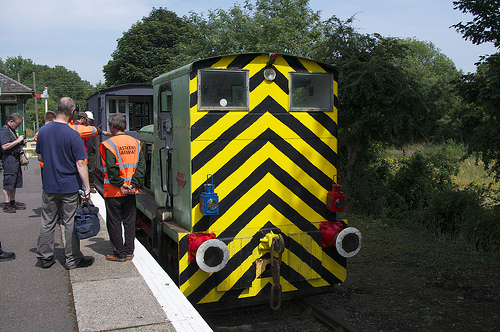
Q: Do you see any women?
A: No, there are no women.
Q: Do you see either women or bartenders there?
A: No, there are no women or bartenders.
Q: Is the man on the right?
A: No, the man is on the left of the image.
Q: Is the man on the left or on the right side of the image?
A: The man is on the left of the image.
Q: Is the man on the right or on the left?
A: The man is on the left of the image.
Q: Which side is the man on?
A: The man is on the left of the image.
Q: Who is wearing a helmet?
A: The man is wearing a helmet.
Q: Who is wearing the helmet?
A: The man is wearing a helmet.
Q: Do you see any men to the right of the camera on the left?
A: Yes, there is a man to the right of the camera.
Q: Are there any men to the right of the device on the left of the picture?
A: Yes, there is a man to the right of the camera.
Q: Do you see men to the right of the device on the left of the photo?
A: Yes, there is a man to the right of the camera.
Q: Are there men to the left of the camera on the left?
A: No, the man is to the right of the camera.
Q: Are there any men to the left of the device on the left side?
A: No, the man is to the right of the camera.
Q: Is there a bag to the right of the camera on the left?
A: No, there is a man to the right of the camera.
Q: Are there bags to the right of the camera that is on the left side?
A: No, there is a man to the right of the camera.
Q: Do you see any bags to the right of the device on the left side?
A: No, there is a man to the right of the camera.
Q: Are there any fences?
A: No, there are no fences.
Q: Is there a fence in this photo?
A: No, there are no fences.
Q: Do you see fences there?
A: No, there are no fences.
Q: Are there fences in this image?
A: No, there are no fences.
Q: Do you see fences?
A: No, there are no fences.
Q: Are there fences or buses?
A: No, there are no fences or buses.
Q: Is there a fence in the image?
A: No, there are no fences.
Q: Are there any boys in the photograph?
A: No, there are no boys.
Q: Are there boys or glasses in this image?
A: No, there are no boys or glasses.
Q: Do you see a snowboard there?
A: No, there are no snowboards.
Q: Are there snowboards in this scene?
A: No, there are no snowboards.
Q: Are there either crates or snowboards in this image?
A: No, there are no snowboards or crates.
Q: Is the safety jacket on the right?
A: No, the safety jacket is on the left of the image.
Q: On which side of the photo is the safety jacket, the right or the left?
A: The safety jacket is on the left of the image.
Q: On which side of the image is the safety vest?
A: The safety vest is on the left of the image.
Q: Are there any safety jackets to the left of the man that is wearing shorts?
A: No, the safety jacket is to the right of the man.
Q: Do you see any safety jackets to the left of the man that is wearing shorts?
A: No, the safety jacket is to the right of the man.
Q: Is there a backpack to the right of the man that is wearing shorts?
A: No, there is a safety jacket to the right of the man.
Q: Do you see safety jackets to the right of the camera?
A: Yes, there is a safety jacket to the right of the camera.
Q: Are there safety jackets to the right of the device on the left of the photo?
A: Yes, there is a safety jacket to the right of the camera.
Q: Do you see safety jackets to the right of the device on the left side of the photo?
A: Yes, there is a safety jacket to the right of the camera.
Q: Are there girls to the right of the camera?
A: No, there is a safety jacket to the right of the camera.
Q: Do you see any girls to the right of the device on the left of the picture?
A: No, there is a safety jacket to the right of the camera.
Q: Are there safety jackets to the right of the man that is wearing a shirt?
A: Yes, there is a safety jacket to the right of the man.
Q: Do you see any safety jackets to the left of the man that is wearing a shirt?
A: No, the safety jacket is to the right of the man.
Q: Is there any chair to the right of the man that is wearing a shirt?
A: No, there is a safety jacket to the right of the man.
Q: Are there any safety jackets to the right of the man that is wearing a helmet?
A: Yes, there is a safety jacket to the right of the man.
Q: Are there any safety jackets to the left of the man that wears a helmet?
A: No, the safety jacket is to the right of the man.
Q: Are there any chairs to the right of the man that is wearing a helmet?
A: No, there is a safety jacket to the right of the man.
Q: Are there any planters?
A: No, there are no planters.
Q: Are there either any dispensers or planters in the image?
A: No, there are no planters or dispensers.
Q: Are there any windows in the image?
A: Yes, there is a window.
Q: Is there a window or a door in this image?
A: Yes, there is a window.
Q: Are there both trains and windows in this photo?
A: Yes, there are both a window and a train.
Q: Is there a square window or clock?
A: Yes, there is a square window.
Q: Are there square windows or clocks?
A: Yes, there is a square window.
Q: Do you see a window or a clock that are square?
A: Yes, the window is square.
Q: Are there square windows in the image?
A: Yes, there is a square window.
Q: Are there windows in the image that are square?
A: Yes, there is a window that is square.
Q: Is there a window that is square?
A: Yes, there is a window that is square.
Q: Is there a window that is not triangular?
A: Yes, there is a square window.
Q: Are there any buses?
A: No, there are no buses.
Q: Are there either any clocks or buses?
A: No, there are no buses or clocks.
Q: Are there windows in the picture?
A: Yes, there is a window.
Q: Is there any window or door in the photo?
A: Yes, there is a window.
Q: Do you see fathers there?
A: No, there are no fathers.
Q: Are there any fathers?
A: No, there are no fathers.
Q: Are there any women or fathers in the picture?
A: No, there are no fathers or women.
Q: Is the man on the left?
A: Yes, the man is on the left of the image.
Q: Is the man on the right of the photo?
A: No, the man is on the left of the image.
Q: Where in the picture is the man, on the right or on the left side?
A: The man is on the left of the image.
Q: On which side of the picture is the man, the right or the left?
A: The man is on the left of the image.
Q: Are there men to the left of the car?
A: Yes, there is a man to the left of the car.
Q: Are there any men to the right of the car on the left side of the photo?
A: No, the man is to the left of the car.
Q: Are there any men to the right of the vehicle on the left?
A: No, the man is to the left of the car.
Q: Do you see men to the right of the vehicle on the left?
A: No, the man is to the left of the car.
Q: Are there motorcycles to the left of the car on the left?
A: No, there is a man to the left of the car.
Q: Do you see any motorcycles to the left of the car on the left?
A: No, there is a man to the left of the car.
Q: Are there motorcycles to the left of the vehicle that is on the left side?
A: No, there is a man to the left of the car.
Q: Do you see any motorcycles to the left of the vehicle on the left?
A: No, there is a man to the left of the car.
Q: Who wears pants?
A: The man wears pants.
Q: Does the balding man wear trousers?
A: Yes, the man wears trousers.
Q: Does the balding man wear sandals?
A: No, the man wears trousers.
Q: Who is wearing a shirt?
A: The man is wearing a shirt.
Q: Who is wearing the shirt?
A: The man is wearing a shirt.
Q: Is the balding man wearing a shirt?
A: Yes, the man is wearing a shirt.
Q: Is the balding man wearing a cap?
A: No, the man is wearing a shirt.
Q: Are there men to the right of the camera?
A: Yes, there is a man to the right of the camera.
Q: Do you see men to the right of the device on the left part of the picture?
A: Yes, there is a man to the right of the camera.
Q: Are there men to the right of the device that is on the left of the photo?
A: Yes, there is a man to the right of the camera.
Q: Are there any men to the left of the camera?
A: No, the man is to the right of the camera.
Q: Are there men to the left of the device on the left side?
A: No, the man is to the right of the camera.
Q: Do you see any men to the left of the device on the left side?
A: No, the man is to the right of the camera.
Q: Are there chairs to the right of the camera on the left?
A: No, there is a man to the right of the camera.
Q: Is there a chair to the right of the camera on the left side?
A: No, there is a man to the right of the camera.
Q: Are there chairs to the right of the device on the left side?
A: No, there is a man to the right of the camera.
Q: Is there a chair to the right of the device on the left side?
A: No, there is a man to the right of the camera.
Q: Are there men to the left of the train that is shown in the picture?
A: Yes, there is a man to the left of the train.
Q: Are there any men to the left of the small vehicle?
A: Yes, there is a man to the left of the train.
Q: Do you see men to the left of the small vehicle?
A: Yes, there is a man to the left of the train.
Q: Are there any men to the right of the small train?
A: No, the man is to the left of the train.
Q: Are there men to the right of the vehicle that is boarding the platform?
A: No, the man is to the left of the train.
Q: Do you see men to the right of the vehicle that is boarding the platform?
A: No, the man is to the left of the train.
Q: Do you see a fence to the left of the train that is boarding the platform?
A: No, there is a man to the left of the train.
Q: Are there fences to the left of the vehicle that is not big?
A: No, there is a man to the left of the train.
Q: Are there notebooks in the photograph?
A: No, there are no notebooks.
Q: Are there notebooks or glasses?
A: No, there are no notebooks or glasses.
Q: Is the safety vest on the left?
A: Yes, the safety vest is on the left of the image.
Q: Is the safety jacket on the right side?
A: No, the safety jacket is on the left of the image.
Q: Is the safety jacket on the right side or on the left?
A: The safety jacket is on the left of the image.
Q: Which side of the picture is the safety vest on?
A: The safety vest is on the left of the image.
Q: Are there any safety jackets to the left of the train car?
A: Yes, there is a safety jacket to the left of the car.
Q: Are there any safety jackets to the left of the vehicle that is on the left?
A: Yes, there is a safety jacket to the left of the car.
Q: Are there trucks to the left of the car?
A: No, there is a safety jacket to the left of the car.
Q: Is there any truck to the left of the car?
A: No, there is a safety jacket to the left of the car.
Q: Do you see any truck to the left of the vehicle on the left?
A: No, there is a safety jacket to the left of the car.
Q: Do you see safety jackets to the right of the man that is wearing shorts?
A: Yes, there is a safety jacket to the right of the man.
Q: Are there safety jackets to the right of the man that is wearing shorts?
A: Yes, there is a safety jacket to the right of the man.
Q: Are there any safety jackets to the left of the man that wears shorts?
A: No, the safety jacket is to the right of the man.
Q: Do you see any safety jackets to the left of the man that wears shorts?
A: No, the safety jacket is to the right of the man.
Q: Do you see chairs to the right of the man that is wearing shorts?
A: No, there is a safety jacket to the right of the man.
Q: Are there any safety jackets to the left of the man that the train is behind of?
A: Yes, there is a safety jacket to the left of the man.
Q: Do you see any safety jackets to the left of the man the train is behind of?
A: Yes, there is a safety jacket to the left of the man.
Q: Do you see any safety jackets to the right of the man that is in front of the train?
A: No, the safety jacket is to the left of the man.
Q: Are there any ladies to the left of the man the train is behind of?
A: No, there is a safety jacket to the left of the man.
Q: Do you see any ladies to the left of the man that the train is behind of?
A: No, there is a safety jacket to the left of the man.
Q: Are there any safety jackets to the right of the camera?
A: Yes, there is a safety jacket to the right of the camera.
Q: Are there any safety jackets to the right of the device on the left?
A: Yes, there is a safety jacket to the right of the camera.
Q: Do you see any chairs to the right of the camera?
A: No, there is a safety jacket to the right of the camera.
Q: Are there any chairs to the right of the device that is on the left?
A: No, there is a safety jacket to the right of the camera.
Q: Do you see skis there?
A: No, there are no skis.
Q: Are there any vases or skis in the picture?
A: No, there are no skis or vases.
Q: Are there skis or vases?
A: No, there are no skis or vases.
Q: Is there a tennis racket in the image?
A: No, there are no rackets.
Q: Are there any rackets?
A: No, there are no rackets.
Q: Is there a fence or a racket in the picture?
A: No, there are no rackets or fences.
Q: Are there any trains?
A: Yes, there is a train.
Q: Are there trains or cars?
A: Yes, there is a train.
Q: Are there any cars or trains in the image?
A: Yes, there is a train.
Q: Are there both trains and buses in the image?
A: No, there is a train but no buses.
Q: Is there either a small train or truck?
A: Yes, there is a small train.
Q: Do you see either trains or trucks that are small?
A: Yes, the train is small.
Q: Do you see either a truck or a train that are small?
A: Yes, the train is small.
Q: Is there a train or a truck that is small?
A: Yes, the train is small.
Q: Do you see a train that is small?
A: Yes, there is a small train.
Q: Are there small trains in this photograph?
A: Yes, there is a small train.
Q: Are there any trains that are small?
A: Yes, there is a train that is small.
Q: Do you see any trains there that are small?
A: Yes, there is a train that is small.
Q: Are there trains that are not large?
A: Yes, there is a small train.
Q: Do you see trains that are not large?
A: Yes, there is a small train.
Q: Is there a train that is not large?
A: Yes, there is a small train.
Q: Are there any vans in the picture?
A: No, there are no vans.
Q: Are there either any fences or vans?
A: No, there are no vans or fences.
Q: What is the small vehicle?
A: The vehicle is a train.